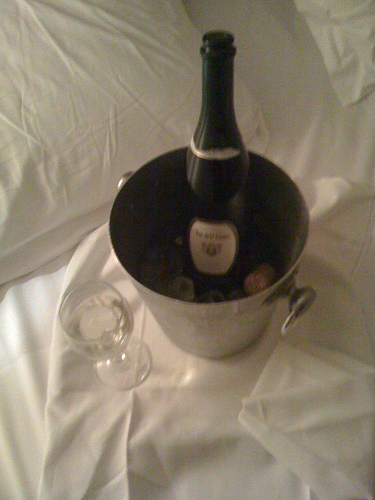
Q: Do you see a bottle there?
A: Yes, there is a bottle.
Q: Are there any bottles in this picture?
A: Yes, there is a bottle.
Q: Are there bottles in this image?
A: Yes, there is a bottle.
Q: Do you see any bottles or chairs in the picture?
A: Yes, there is a bottle.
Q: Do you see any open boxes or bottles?
A: Yes, there is an open bottle.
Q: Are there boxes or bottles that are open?
A: Yes, the bottle is open.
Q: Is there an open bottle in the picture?
A: Yes, there is an open bottle.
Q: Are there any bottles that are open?
A: Yes, there is a bottle that is open.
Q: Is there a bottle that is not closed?
A: Yes, there is a open bottle.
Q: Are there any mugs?
A: No, there are no mugs.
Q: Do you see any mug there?
A: No, there are no mugs.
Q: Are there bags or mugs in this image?
A: No, there are no mugs or bags.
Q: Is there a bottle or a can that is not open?
A: No, there is a bottle but it is open.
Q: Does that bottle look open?
A: Yes, the bottle is open.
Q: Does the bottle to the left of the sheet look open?
A: Yes, the bottle is open.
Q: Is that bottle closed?
A: No, the bottle is open.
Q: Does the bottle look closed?
A: No, the bottle is open.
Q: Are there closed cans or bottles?
A: No, there is a bottle but it is open.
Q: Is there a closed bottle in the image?
A: No, there is a bottle but it is open.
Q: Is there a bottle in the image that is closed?
A: No, there is a bottle but it is open.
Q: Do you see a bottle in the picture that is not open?
A: No, there is a bottle but it is open.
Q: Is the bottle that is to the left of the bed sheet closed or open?
A: The bottle is open.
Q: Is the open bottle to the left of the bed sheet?
A: Yes, the bottle is to the left of the bed sheet.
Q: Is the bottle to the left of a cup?
A: No, the bottle is to the left of the bed sheet.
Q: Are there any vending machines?
A: No, there are no vending machines.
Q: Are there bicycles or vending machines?
A: No, there are no vending machines or bicycles.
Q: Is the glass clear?
A: Yes, the glass is clear.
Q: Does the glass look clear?
A: Yes, the glass is clear.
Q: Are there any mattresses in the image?
A: No, there are no mattresses.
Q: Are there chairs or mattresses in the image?
A: No, there are no mattresses or chairs.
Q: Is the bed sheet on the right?
A: Yes, the bed sheet is on the right of the image.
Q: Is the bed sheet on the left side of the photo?
A: No, the bed sheet is on the right of the image.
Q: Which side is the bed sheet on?
A: The bed sheet is on the right of the image.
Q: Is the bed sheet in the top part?
A: Yes, the bed sheet is in the top of the image.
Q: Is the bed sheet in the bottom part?
A: No, the bed sheet is in the top of the image.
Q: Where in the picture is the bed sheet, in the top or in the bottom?
A: The bed sheet is in the top of the image.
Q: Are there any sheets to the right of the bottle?
A: Yes, there is a sheet to the right of the bottle.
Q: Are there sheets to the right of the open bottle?
A: Yes, there is a sheet to the right of the bottle.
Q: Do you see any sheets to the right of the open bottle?
A: Yes, there is a sheet to the right of the bottle.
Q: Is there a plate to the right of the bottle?
A: No, there is a sheet to the right of the bottle.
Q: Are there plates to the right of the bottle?
A: No, there is a sheet to the right of the bottle.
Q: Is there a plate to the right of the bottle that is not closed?
A: No, there is a sheet to the right of the bottle.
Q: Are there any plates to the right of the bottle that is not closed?
A: No, there is a sheet to the right of the bottle.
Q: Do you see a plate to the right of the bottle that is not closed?
A: No, there is a sheet to the right of the bottle.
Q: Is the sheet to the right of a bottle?
A: Yes, the sheet is to the right of a bottle.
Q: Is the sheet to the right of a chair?
A: No, the sheet is to the right of a bottle.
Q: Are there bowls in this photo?
A: No, there are no bowls.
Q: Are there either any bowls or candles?
A: No, there are no bowls or candles.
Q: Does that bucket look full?
A: Yes, the bucket is full.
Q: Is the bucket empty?
A: No, the bucket is full.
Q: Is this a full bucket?
A: Yes, this is a full bucket.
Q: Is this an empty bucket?
A: No, this is a full bucket.